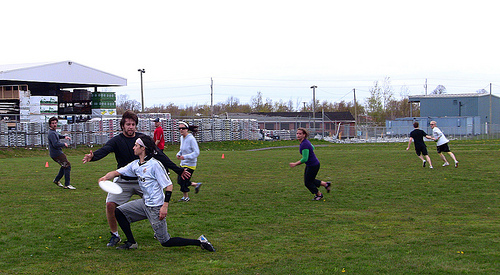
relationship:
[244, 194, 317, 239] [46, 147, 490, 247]
grass in field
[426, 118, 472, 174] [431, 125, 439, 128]
man has beard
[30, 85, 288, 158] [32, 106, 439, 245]
lot behind players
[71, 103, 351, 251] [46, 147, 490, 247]
people in field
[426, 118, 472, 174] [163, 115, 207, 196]
man with woman